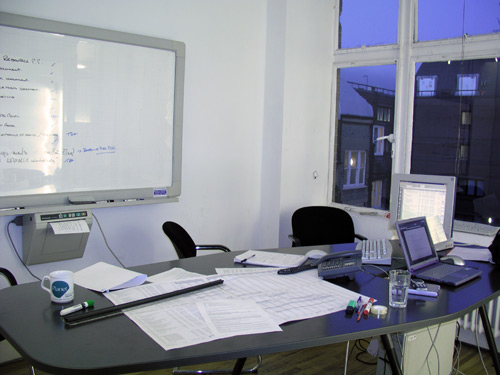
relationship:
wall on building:
[413, 96, 464, 177] [357, 54, 499, 223]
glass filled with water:
[388, 270, 412, 308] [387, 285, 409, 305]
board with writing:
[0, 13, 186, 217] [6, 59, 45, 109]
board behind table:
[0, 13, 186, 217] [0, 237, 499, 374]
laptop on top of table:
[393, 214, 481, 283] [0, 237, 499, 374]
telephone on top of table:
[320, 250, 360, 278] [0, 237, 499, 374]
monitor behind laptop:
[387, 172, 454, 242] [393, 214, 481, 283]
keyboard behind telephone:
[360, 237, 390, 264] [317, 249, 358, 274]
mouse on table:
[304, 247, 323, 256] [0, 237, 499, 374]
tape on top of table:
[369, 304, 389, 316] [0, 237, 499, 374]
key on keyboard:
[426, 266, 431, 271] [416, 261, 458, 279]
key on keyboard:
[368, 244, 375, 250] [360, 240, 391, 264]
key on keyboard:
[371, 240, 376, 245] [357, 239, 389, 264]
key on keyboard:
[380, 239, 385, 245] [360, 238, 394, 266]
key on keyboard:
[369, 244, 374, 248] [360, 237, 390, 264]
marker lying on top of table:
[60, 300, 95, 315] [0, 237, 499, 374]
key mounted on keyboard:
[376, 250, 381, 256] [358, 233, 394, 265]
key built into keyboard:
[437, 271, 439, 274] [403, 248, 483, 284]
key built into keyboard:
[443, 265, 447, 271] [416, 260, 465, 281]